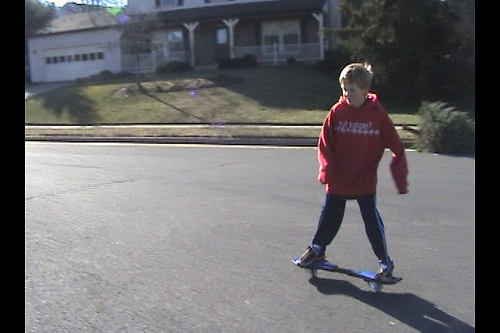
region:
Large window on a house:
[165, 31, 182, 51]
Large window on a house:
[214, 26, 235, 43]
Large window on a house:
[255, 20, 287, 60]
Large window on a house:
[278, 18, 306, 68]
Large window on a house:
[140, 27, 167, 65]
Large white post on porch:
[311, 6, 334, 63]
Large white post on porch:
[219, 15, 242, 65]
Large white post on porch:
[178, 20, 203, 79]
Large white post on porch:
[126, 16, 154, 77]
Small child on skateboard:
[288, 36, 420, 314]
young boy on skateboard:
[289, 59, 410, 288]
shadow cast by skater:
[308, 272, 472, 331]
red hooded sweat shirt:
[317, 92, 411, 199]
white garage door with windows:
[39, 40, 108, 85]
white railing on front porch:
[227, 43, 325, 62]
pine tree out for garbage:
[400, 103, 477, 155]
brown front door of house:
[210, 20, 232, 60]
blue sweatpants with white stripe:
[309, 193, 396, 275]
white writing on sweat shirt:
[330, 118, 380, 139]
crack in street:
[32, 160, 142, 220]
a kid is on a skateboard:
[295, 62, 414, 291]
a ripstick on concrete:
[295, 251, 400, 297]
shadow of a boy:
[308, 273, 467, 331]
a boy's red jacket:
[313, 93, 408, 198]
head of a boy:
[342, 62, 372, 110]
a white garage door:
[40, 42, 105, 78]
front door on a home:
[214, 26, 231, 68]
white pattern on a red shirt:
[323, 119, 385, 136]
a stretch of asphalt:
[25, 141, 475, 332]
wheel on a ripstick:
[366, 279, 382, 292]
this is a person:
[302, 55, 414, 287]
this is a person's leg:
[289, 175, 348, 275]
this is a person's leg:
[355, 196, 403, 296]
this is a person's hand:
[375, 105, 414, 197]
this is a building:
[27, 2, 125, 85]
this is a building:
[121, 0, 335, 67]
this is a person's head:
[329, 56, 373, 113]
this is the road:
[36, 233, 200, 314]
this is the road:
[50, 140, 195, 203]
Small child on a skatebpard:
[285, 43, 400, 332]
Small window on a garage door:
[42, 51, 52, 68]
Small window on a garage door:
[49, 53, 60, 68]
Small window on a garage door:
[54, 51, 64, 67]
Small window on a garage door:
[70, 50, 78, 70]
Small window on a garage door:
[78, 48, 90, 69]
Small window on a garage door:
[89, 52, 96, 62]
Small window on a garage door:
[97, 46, 109, 58]